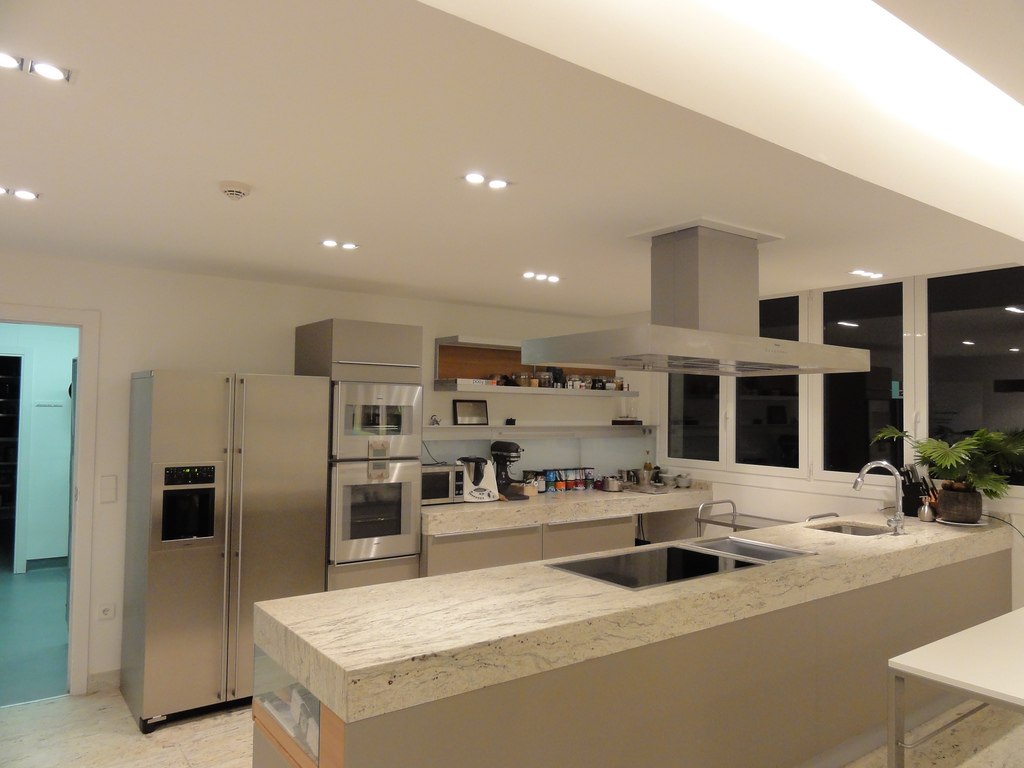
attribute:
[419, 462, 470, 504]
microwave — silver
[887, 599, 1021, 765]
table — white